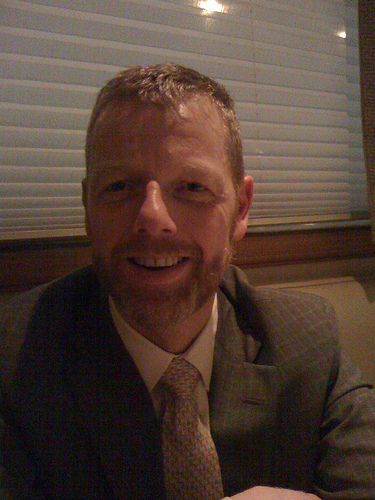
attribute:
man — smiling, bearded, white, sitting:
[1, 60, 374, 498]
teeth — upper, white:
[128, 253, 185, 269]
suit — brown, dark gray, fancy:
[0, 261, 372, 500]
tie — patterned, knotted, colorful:
[156, 356, 224, 500]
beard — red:
[86, 246, 228, 327]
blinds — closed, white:
[0, 0, 369, 238]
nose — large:
[126, 177, 179, 237]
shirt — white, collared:
[106, 286, 221, 441]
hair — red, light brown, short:
[81, 59, 243, 187]